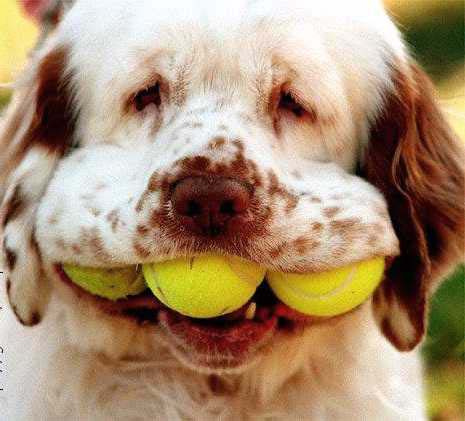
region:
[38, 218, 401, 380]
three tennis balls in dog's mouth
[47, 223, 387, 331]
bottom of three tennis balls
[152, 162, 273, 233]
dog nose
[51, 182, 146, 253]
brown spots on face of dog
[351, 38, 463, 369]
floppy dog ear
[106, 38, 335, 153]
two down turned dog ears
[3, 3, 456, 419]
brown and white dog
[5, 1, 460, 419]
brown and white dog with three tennis balls in mouth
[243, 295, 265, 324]
white bottom tooth of dog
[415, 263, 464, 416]
blurred green background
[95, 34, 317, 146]
eyes of a dog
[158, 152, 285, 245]
nose of a dog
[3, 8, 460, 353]
head of a dog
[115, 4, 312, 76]
forehead of a dog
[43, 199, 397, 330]
three tennis ball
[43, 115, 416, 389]
the mouth of a dog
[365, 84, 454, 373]
ear of a dog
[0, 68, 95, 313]
ear of a dog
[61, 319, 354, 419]
neck of a dog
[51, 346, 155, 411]
fur of a dog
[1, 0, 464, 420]
dog with tennis balls in mouth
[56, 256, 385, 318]
three yellow tennis balls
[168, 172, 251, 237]
dark brown dog nose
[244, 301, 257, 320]
sharp lower tooth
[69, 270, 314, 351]
pink lining of mouth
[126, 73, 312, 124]
black eyes on face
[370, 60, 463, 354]
floppy furry brown ear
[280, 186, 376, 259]
brown spots on white muzzle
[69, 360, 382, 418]
long white fur on neck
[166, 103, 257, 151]
brown spots on snout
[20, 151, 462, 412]
the dog has three balls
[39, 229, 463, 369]
the dog has balls in his mouth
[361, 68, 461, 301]
the dog has brown ears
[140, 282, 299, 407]
the dog has teeth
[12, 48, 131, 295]
the dog has brown spotted ears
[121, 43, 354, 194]
the dog has small eyes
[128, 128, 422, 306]
the dog has a spotted nose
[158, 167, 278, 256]
the dog has a brown nose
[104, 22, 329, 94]
the dog has a white forehead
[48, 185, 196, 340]
the balls are green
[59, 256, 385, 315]
three tennis balls in the dog's mouth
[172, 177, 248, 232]
brown dog nose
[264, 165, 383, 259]
brown spots on the dog's face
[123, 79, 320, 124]
the dog's eyes are open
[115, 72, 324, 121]
the dog's eyes are droopy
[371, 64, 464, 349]
long brown dog ear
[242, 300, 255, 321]
large white tooth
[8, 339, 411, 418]
the dog fur is white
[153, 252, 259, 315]
the tennis ball is yellow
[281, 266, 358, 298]
white seem on the ball